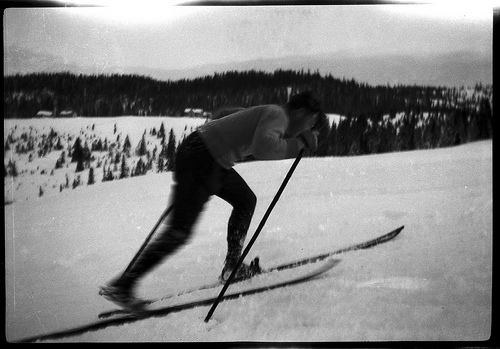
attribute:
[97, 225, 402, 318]
skies — long, black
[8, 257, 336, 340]
skies — long, black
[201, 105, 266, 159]
sweater — medium, colored, warm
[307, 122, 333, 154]
glove — toasty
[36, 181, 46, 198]
tree — sparse, planted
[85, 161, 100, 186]
tree — sparse, planted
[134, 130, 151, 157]
tree — sparse, planted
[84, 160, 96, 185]
tree — sparse, planted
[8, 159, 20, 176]
tree — sparse, planted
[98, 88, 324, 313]
skier — one, cross country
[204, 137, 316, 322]
pole — long, black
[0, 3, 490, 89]
clouds — low-lying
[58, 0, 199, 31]
sun — bright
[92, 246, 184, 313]
boot — ski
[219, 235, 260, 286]
boot — ski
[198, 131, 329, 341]
pole — ski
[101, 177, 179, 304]
pole — ski